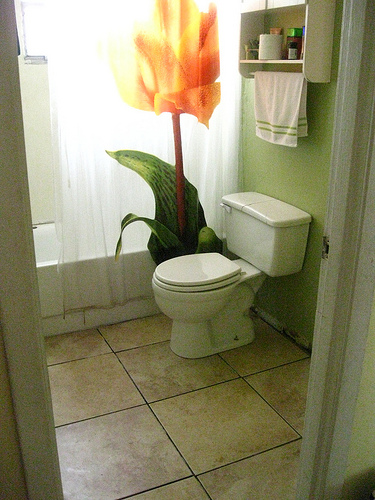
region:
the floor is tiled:
[86, 338, 227, 494]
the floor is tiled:
[92, 354, 223, 476]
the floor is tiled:
[55, 320, 211, 488]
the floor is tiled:
[82, 352, 218, 474]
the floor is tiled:
[78, 353, 208, 488]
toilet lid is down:
[150, 247, 241, 320]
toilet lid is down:
[144, 244, 231, 309]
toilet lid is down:
[150, 248, 251, 307]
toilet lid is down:
[145, 252, 265, 313]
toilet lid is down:
[138, 243, 235, 306]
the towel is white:
[247, 68, 312, 153]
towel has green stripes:
[247, 70, 311, 151]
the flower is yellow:
[117, 1, 229, 132]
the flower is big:
[105, 1, 229, 134]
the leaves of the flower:
[96, 136, 220, 259]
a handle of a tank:
[217, 195, 232, 218]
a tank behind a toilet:
[211, 184, 313, 280]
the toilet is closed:
[144, 241, 260, 366]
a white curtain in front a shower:
[46, 5, 258, 317]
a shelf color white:
[234, 2, 335, 92]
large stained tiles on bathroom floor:
[28, 298, 310, 496]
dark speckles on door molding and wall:
[0, 2, 60, 493]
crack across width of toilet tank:
[217, 186, 307, 276]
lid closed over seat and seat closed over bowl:
[150, 248, 260, 355]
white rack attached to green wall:
[232, 0, 335, 347]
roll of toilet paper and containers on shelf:
[235, 8, 304, 59]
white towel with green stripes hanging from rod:
[240, 66, 309, 145]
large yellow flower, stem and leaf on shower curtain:
[45, 0, 228, 315]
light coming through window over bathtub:
[11, 0, 155, 337]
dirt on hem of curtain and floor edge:
[58, 291, 313, 353]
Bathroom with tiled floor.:
[4, 3, 369, 491]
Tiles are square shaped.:
[142, 369, 298, 481]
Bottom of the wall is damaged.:
[251, 303, 312, 359]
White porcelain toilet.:
[150, 184, 310, 360]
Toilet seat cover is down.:
[145, 248, 240, 297]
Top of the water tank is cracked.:
[216, 194, 308, 209]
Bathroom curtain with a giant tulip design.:
[60, 0, 240, 306]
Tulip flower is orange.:
[124, 2, 223, 123]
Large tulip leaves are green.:
[101, 144, 221, 264]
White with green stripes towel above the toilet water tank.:
[244, 67, 308, 148]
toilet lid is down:
[147, 245, 239, 294]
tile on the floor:
[40, 304, 307, 499]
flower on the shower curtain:
[43, 1, 264, 309]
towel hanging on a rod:
[248, 66, 308, 150]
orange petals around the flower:
[96, 0, 225, 130]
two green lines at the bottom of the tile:
[254, 118, 300, 137]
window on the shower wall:
[21, 9, 58, 65]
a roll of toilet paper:
[252, 30, 287, 58]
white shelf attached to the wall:
[233, 2, 338, 86]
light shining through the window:
[19, 5, 60, 59]